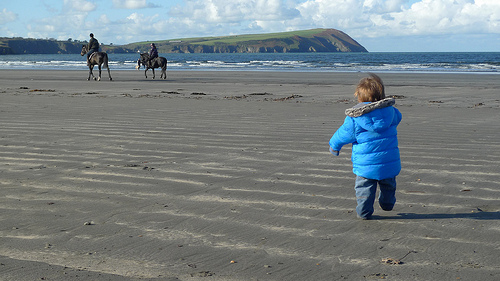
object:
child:
[326, 72, 401, 221]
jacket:
[328, 102, 402, 180]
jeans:
[353, 175, 397, 218]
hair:
[353, 72, 386, 102]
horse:
[138, 52, 168, 79]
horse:
[81, 44, 115, 81]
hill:
[0, 27, 368, 53]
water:
[0, 53, 500, 70]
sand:
[13, 74, 455, 269]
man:
[146, 43, 158, 68]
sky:
[180, 2, 466, 41]